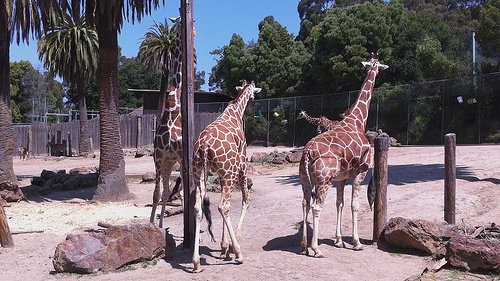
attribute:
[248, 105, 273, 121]
street sign — green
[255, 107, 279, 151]
pole — black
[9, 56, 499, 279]
cage — metal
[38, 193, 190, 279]
rock — large, sandstone, brown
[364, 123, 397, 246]
post — wooden, short, brown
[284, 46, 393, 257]
giraffe — fat, looking, standing, tall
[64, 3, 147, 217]
palm tree — large, standing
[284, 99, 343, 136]
giraffe — walking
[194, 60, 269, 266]
giraffe — stepping, leaving, walking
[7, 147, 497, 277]
ground — sand, dirt, brown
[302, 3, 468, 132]
oak tree — green, large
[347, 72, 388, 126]
neck — long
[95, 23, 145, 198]
trunk — brown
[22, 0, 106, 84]
leaves — green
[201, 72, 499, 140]
fence — metal, chain link